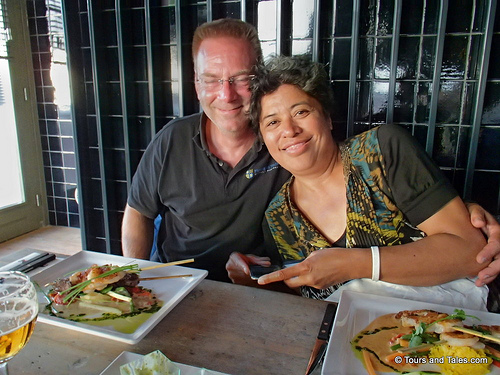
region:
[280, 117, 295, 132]
the nose of the white woman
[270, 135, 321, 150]
the mouth of the white woman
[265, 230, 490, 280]
the hand of the white woman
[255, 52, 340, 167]
the head of the white woman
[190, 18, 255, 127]
the head of the white man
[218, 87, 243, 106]
the nose of the white man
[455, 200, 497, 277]
the hand of the white man holding the woman's elbow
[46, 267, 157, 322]
vegetables in a place placed on a table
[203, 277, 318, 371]
a wooden table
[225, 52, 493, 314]
A woman leaning toward someone else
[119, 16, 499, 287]
A man with his arm around someone else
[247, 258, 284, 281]
A cell phone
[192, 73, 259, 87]
A pair of glasses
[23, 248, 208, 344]
A square white dinner plate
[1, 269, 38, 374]
A half full stemmed glass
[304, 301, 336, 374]
A steak knife with a black handle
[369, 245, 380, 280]
A white bracelet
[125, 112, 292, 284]
A black polo shirt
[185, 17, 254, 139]
A man with glasses blinks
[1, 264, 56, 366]
A glass with beer in it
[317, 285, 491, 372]
Food on a white plate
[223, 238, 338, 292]
Hands holding a cell phone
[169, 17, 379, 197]
A man and woman smile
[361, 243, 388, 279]
A white bracelet on a woman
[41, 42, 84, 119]
Sun reflecting off of a wall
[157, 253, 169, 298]
There are chop sticks here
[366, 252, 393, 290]
This woman has a white bracelet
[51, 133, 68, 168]
There is some blue tile that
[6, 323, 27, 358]
There is a beer that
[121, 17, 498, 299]
man and woman sitting together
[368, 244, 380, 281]
white band around woman's left wrist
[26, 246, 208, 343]
large white plate sitting on the table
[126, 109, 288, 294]
gray shirt the man is wearing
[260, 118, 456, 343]
green, yellow top the woman is wearing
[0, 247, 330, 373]
wood tabletop food is sitting on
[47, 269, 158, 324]
food sitting on a white plate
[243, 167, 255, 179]
white logo on the gray shirt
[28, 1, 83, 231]
gray and white tile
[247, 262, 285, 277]
cell phone in the woman's hands